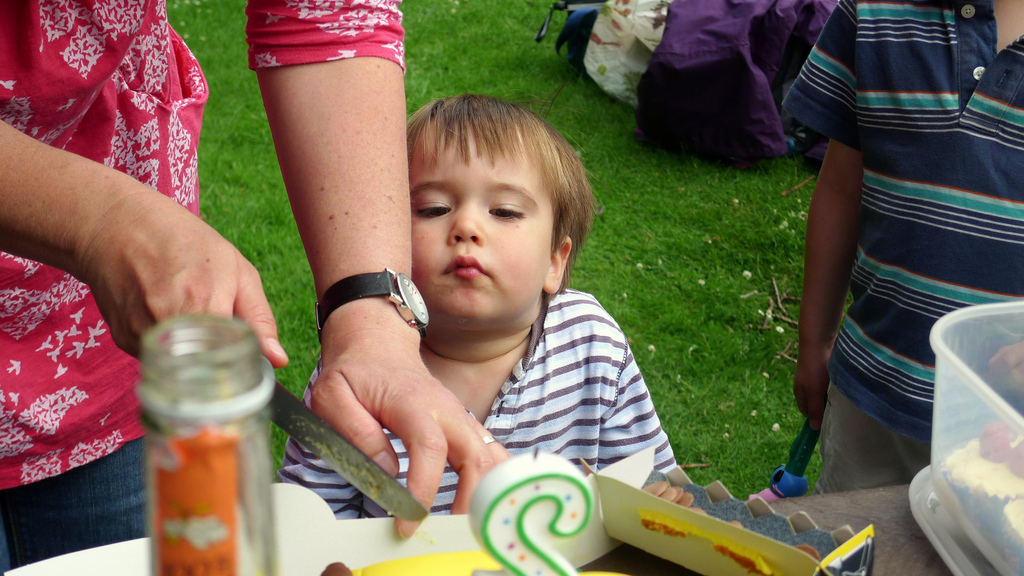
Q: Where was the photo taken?
A: At an outdoor birthday party.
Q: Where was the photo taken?
A: At a birthday party.